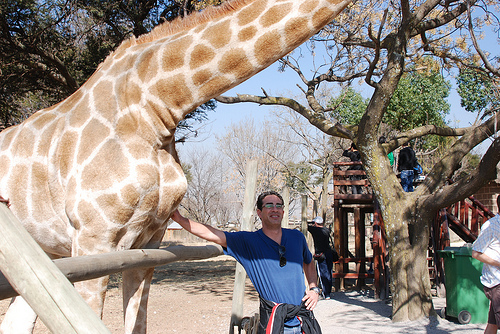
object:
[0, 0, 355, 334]
giraffe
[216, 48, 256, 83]
spot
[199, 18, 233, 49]
spot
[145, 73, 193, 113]
spot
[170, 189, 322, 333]
man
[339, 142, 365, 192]
child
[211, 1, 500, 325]
tree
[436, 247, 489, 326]
trash can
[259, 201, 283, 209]
glasses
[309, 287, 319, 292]
watch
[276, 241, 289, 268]
sunglasses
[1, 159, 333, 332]
fence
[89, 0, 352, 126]
neck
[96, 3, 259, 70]
mane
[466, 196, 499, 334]
man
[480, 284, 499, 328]
shorts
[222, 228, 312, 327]
jacket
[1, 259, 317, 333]
gravel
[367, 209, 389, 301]
post